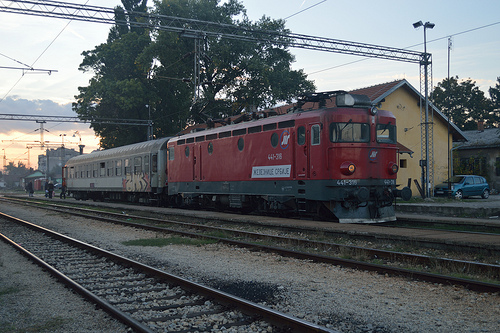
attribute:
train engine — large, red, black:
[166, 104, 397, 223]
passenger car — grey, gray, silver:
[65, 137, 166, 206]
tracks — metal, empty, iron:
[382, 218, 497, 237]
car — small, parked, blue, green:
[433, 174, 488, 200]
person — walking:
[58, 182, 68, 200]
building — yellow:
[362, 77, 467, 201]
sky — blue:
[0, 1, 499, 93]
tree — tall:
[73, 1, 316, 147]